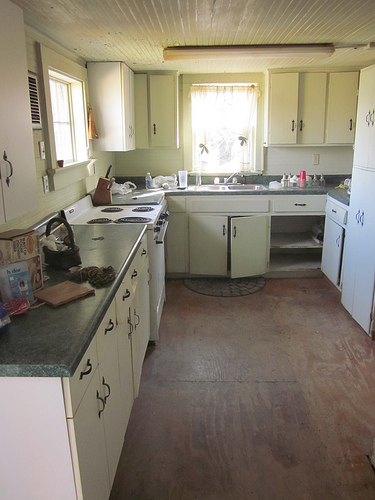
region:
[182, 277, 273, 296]
a rug on the floor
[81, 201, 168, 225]
the range of the stove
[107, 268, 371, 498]
the hardwood floor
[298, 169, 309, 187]
red plastic cups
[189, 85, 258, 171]
the window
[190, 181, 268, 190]
the sink of the kitchen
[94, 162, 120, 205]
a knife block sitting on the counter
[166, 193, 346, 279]
white cupboards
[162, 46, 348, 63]
a light hanging on the ceiling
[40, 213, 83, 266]
a brown basket on the counter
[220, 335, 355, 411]
brown wood floor of the kitchen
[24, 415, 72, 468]
white surface of the kitchen cabinet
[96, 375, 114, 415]
black metal handles of the cabinets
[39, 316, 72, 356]
green formica surface of the counter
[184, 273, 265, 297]
a floor mat in front of the sink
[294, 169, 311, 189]
a stack of red cups on the counter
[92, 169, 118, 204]
a brown wood knife block on the counter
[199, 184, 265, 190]
grey metal basins of the sink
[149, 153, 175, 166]
white wall of the kitchen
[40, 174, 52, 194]
white electrical outlet on the wall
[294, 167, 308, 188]
Red cups on the kitchen counter.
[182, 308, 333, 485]
The flooring is wood.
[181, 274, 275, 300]
A mat in front of the cabinet.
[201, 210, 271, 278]
The cabinet door is open.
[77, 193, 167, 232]
A stove in the kitchen.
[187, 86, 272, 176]
Curtains over the window.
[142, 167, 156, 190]
A water bottle on the countertop.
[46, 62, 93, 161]
A window in the kitchen.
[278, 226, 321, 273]
The cabinet does not have a door.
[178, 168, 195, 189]
A clear container on the countertop